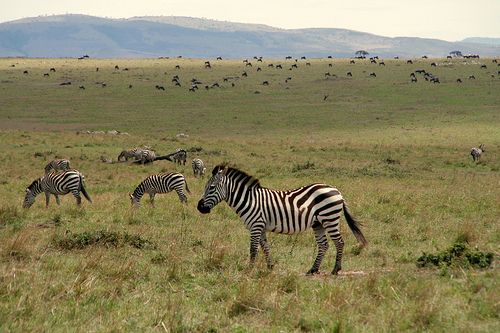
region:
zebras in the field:
[22, 134, 394, 311]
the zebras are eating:
[10, 147, 193, 240]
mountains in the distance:
[36, 14, 459, 100]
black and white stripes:
[24, 168, 358, 260]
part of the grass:
[425, 283, 439, 291]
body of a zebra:
[273, 200, 298, 202]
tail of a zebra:
[347, 212, 354, 228]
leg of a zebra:
[248, 193, 276, 255]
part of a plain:
[431, 167, 474, 187]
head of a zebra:
[211, 195, 247, 210]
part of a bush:
[61, 188, 137, 264]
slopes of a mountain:
[363, 136, 395, 155]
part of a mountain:
[235, 103, 254, 115]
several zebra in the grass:
[16, 135, 401, 312]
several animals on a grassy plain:
[8, 40, 485, 320]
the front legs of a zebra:
[236, 219, 273, 281]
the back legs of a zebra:
[298, 225, 345, 291]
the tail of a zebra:
[346, 200, 373, 257]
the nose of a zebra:
[192, 198, 207, 213]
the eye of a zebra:
[208, 182, 215, 192]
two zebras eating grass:
[17, 166, 190, 225]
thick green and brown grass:
[260, 107, 458, 175]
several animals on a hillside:
[143, 59, 300, 110]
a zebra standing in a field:
[196, 165, 367, 280]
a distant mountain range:
[0, 12, 499, 60]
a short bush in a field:
[410, 240, 492, 271]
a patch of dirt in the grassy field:
[0, 118, 107, 130]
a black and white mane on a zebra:
[216, 165, 263, 186]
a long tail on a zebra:
[341, 199, 367, 251]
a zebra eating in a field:
[129, 172, 190, 212]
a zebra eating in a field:
[20, 167, 87, 212]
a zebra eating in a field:
[45, 155, 65, 170]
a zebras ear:
[220, 163, 229, 175]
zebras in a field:
[11, 56, 466, 316]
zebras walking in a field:
[13, 60, 498, 330]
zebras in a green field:
[16, 73, 498, 331]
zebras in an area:
[30, 76, 453, 329]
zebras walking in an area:
[26, 68, 461, 325]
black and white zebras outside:
[33, 73, 448, 314]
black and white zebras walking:
[18, 36, 447, 323]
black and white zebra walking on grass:
[7, 69, 460, 326]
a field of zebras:
[29, 46, 391, 331]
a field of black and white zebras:
[7, 70, 470, 330]